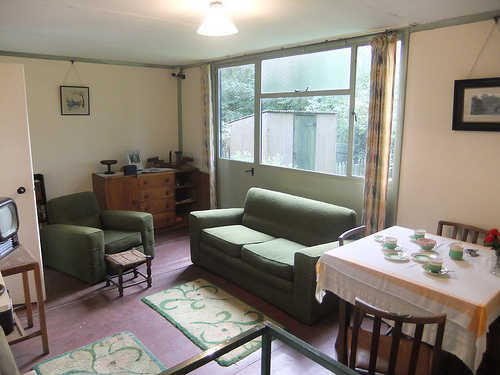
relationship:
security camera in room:
[170, 70, 187, 80] [110, 99, 471, 358]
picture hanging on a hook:
[59, 85, 91, 117] [69, 60, 75, 66]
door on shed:
[294, 114, 317, 172] [230, 108, 336, 173]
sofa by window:
[187, 184, 356, 326] [216, 44, 374, 178]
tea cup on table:
[431, 256, 444, 272] [315, 226, 499, 373]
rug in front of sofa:
[143, 277, 286, 365] [187, 184, 356, 326]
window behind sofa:
[216, 44, 374, 178] [187, 184, 356, 326]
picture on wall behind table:
[452, 79, 498, 130] [315, 226, 499, 373]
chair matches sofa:
[42, 191, 153, 283] [187, 184, 356, 326]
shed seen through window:
[230, 108, 336, 173] [216, 44, 374, 178]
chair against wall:
[436, 217, 492, 242] [398, 19, 497, 244]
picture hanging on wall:
[452, 79, 498, 130] [398, 19, 497, 244]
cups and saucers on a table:
[376, 227, 478, 279] [315, 226, 499, 373]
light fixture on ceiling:
[197, 1, 237, 38] [2, 2, 499, 67]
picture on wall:
[452, 79, 498, 130] [398, 19, 497, 244]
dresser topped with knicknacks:
[95, 171, 174, 225] [100, 148, 165, 173]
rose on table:
[485, 227, 499, 246] [315, 226, 499, 373]